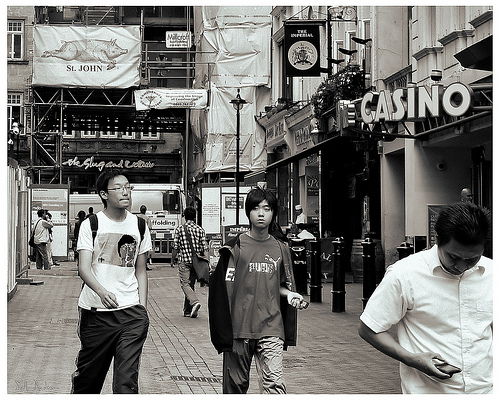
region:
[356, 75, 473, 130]
the sign says CASINO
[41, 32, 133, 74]
the sign has a pig on it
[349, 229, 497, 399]
the boy is wearing a white shirt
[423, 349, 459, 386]
the man is texting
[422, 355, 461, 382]
the man has a cel phone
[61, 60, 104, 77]
the sign says st. john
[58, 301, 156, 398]
the guy is wearing black pants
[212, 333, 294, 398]
the guy is wearing wrinkled pants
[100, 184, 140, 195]
the guy is wearing glasses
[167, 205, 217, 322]
the guy is wearing a plaid shirt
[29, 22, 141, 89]
A banner with a picture of a pig on it.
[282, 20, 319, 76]
A banner with a seal on it.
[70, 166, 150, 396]
A person wearing a Beatles shirt.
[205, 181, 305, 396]
A person walking down the street.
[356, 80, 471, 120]
A large sign for a casino.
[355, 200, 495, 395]
A guy looking down at his cellphone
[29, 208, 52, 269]
A person standing on the street.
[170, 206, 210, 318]
A person walking down the street.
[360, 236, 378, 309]
A post.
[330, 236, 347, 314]
A post.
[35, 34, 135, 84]
white flag with a pig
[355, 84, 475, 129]
neon casino sign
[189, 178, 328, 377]
shaggy haired kid walking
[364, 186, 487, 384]
man walking and checking his phone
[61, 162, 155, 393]
man in glasses and a backpack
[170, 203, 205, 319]
man in flannel and wearing a backpack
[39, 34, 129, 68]
pig on a flag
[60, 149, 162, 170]
cursive neon store sign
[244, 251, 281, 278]
white puma logo on t-shirt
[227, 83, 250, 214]
tall black lamppost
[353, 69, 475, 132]
sign advertising a casino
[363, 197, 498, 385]
man looking down at his cell phone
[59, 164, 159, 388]
man walking down the street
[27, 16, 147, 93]
pig drawn on a sign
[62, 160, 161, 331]
man in a t-shirt wearing a backpack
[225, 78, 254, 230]
lamp post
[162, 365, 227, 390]
grate on a street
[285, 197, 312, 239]
man wearing a white hat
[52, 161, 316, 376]
two people walking down the street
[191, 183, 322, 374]
a man in a t-shirt holding a cell phone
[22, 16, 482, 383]
an innercity brick street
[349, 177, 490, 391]
a man looking at his cellphone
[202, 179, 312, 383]
a young man with a puma tshirt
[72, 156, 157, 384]
a man with glasses and a backpack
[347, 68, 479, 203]
a casino sign on a building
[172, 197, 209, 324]
a man carrying a passenger bag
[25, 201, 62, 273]
two men talking on the street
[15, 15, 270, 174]
construction coverings on a building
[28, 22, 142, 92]
a pig poster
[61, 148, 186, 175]
an electric sign